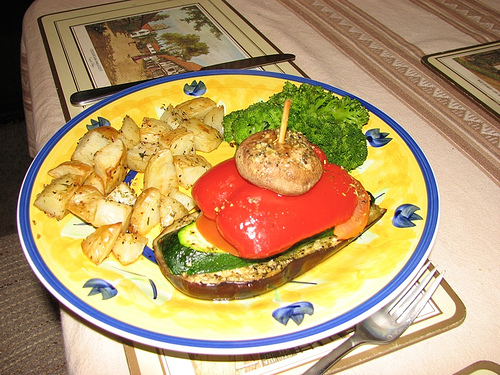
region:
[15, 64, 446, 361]
A meal on a colorful plate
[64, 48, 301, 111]
A knife to the left of the plate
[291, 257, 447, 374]
A fork to the right of the plate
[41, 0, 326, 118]
A picture on the placemat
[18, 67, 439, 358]
A yellow plate with blue flowers and border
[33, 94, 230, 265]
Spicy fried potatoes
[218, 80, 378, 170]
Broccoli next to the potatoes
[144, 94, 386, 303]
Tomato, mushroom, pepper and zucchini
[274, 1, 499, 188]
Southwestern design on the tablecloth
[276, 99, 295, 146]
A stick holding the food together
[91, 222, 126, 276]
potato is sliced up and seasoned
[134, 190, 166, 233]
potato is sliced up and seasoned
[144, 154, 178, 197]
potato is sliced up and seasoned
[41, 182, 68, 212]
potato is sliced up and seasoned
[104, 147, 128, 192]
potato is sliced up and seasoned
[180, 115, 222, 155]
potato is sliced up and seasoned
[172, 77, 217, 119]
potato is sliced up and seasoned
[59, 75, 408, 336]
food on yellow plate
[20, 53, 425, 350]
plate has a blue rim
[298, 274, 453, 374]
silver fork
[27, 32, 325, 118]
a silver butter knife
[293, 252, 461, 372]
a silver fork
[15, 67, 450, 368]
a yellow and blue plate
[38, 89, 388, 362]
a plate with food on it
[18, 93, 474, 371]
a yellow and blue plate on a table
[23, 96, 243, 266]
a plate with potatos on it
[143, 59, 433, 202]
a plate with broccoli on it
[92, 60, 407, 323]
a plate with a pepper on it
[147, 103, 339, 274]
a plate with a mushroom on it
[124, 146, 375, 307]
a plate with eggplant on it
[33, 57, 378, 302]
Food sitting on plate on table.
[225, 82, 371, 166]
Broccoli sitting on plate.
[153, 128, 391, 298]
Vegetable sandwich sitting on plate.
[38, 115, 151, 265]
Roasted potatoes sitting on plate.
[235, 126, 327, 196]
Mushroom sitting on red pepper.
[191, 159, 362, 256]
Red pepper slice sitting on zucchini.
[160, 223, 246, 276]
Zucchini sitting on on slice of egg plant.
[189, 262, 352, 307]
Edge of egg plant lying on plate.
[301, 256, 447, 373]
Fork lying on table next to plate.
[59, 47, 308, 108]
Knife lying on table next to plate.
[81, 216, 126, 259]
potatoe on a plate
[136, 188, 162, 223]
potatoe on a plate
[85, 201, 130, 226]
potatoe on a plate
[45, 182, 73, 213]
potatoe on a plate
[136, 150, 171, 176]
potatoe on a plate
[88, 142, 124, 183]
potatoe on a plate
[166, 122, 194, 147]
potatoe on a plate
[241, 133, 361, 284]
food on a plate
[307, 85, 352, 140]
food on a plate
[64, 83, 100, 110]
fork on a table